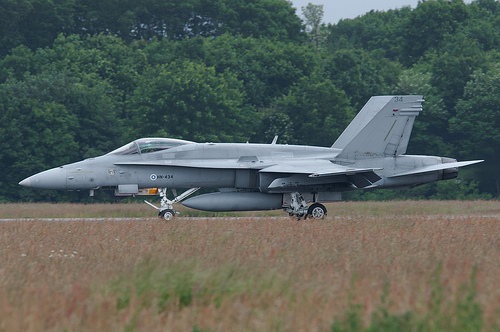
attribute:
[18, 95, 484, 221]
jet — sleek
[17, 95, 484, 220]
plane — military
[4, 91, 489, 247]
jet — long, gray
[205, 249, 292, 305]
grass — green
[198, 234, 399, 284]
field — brown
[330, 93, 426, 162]
grey tail — large 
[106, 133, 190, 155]
enclosure — glass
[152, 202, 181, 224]
wheel — small 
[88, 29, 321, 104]
trees — thick 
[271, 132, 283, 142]
rudder — small 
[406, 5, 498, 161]
leaves — green